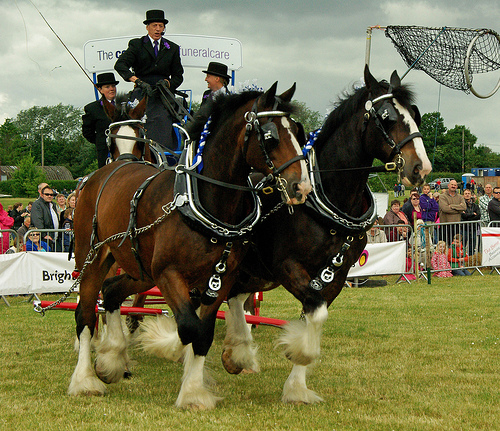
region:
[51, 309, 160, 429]
White hooves on a horse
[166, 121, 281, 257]
Black Bridle on a horse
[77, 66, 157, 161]
Woman in a black suit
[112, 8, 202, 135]
Man in a black suit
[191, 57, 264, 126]
Person smiling in a hat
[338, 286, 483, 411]
Brown and green grass on the ground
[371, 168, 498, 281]
Crowd watching horses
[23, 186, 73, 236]
Man in sunglasses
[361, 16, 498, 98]
Net above a field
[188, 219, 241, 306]
Silver and black on a horse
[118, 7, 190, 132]
Man in a top hat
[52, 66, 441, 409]
Two large clydesdale horses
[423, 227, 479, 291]
Children watching through the fence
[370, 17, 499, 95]
Black net on a pole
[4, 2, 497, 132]
Grey cloudy sky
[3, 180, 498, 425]
Big green lawn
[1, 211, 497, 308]
Temporary metal gate with banners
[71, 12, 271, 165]
three people on a wagon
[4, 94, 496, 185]
Green trees on horizon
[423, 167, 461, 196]
Green SUV in background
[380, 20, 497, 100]
metal rim chain link net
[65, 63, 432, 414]
two horses performing in a show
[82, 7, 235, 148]
three men in suits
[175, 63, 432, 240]
two horses bridled mouths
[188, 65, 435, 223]
heads on two horses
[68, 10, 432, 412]
brown and black horses running in a field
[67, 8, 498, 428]
two horses pulling three men on a carriage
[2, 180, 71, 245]
people watching the horse show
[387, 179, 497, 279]
spectators observing the funeralcare show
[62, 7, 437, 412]
funeral care directors in a horse show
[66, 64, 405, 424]
two horses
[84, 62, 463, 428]
two black brown and white horses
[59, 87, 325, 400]
a horse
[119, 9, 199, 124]
a man with a black hat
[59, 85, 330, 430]
a black brown and white horse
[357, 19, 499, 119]
a black net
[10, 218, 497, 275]
a silver fence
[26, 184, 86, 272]
a man wearing sunglasses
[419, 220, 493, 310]
two small children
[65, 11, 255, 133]
three people wearing black hats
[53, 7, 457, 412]
men riding clydesdale horses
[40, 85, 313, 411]
brown clydesdale horse with white feet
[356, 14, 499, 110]
cone shaped net by horses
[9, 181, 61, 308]
people watching horses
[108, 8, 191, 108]
man in a top hat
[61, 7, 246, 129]
three men riding horses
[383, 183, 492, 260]
people watching brown horses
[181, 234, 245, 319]
bells on a brown horse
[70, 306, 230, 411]
white hooves on horses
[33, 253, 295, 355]
red bars of a horse drawn carriage